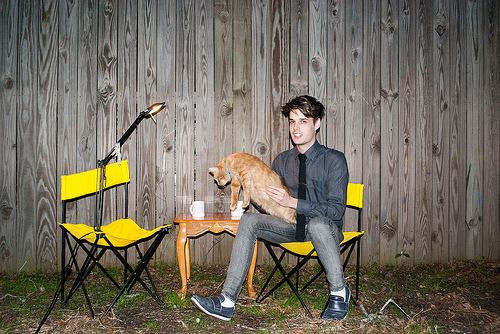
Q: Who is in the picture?
A: A man.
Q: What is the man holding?
A: A cat.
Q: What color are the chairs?
A: Yellow.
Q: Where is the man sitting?
A: In a chair.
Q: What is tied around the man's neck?
A: A tie.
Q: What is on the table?
A: Coffee mugs.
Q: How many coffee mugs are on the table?
A: Two.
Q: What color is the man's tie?
A: Black.